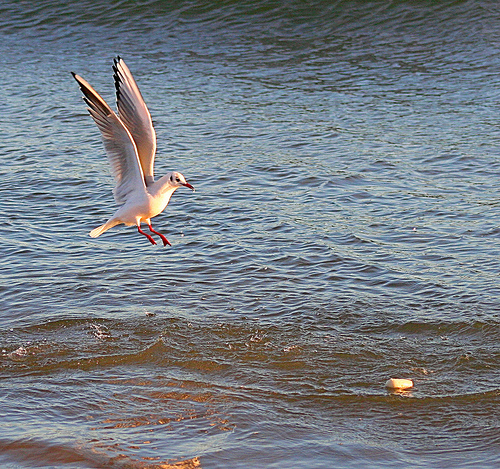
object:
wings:
[111, 54, 156, 185]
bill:
[183, 185, 192, 189]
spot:
[168, 175, 171, 183]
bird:
[71, 56, 194, 246]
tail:
[88, 216, 118, 236]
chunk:
[386, 377, 414, 389]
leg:
[134, 217, 150, 238]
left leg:
[143, 219, 163, 237]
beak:
[182, 183, 195, 190]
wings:
[71, 71, 146, 207]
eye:
[176, 179, 180, 182]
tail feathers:
[88, 220, 117, 236]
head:
[168, 171, 194, 189]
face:
[166, 162, 189, 200]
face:
[168, 171, 186, 186]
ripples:
[205, 291, 312, 354]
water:
[0, 0, 500, 469]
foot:
[147, 234, 157, 245]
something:
[369, 366, 429, 405]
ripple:
[0, 0, 500, 469]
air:
[178, 204, 222, 233]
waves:
[24, 314, 252, 378]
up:
[112, 55, 140, 94]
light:
[75, 400, 235, 466]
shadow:
[14, 1, 498, 93]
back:
[7, 8, 495, 136]